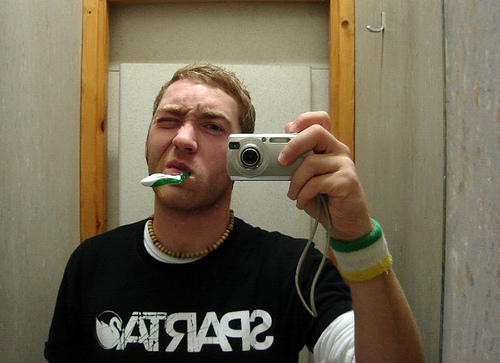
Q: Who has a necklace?
A: The man.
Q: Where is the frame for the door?
A: Around the door.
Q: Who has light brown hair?
A: The man.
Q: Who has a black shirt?
A: The man.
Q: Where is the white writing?
A: On the shirt.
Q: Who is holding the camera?
A: The man.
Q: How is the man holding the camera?
A: With his fingers.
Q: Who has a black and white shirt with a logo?
A: The man.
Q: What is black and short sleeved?
A: A shirt.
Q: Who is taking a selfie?
A: The man.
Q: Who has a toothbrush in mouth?
A: The man.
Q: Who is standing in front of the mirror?
A: The man.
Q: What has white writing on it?
A: A shirt.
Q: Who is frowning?
A: The man.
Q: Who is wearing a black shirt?
A: The man.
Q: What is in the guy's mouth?
A: Toothbrush.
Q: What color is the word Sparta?
A: White.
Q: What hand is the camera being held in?
A: Left.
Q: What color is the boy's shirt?
A: Black.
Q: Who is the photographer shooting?
A: Himself.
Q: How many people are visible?
A: 1.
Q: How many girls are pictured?
A: Zero.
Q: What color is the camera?
A: Silver.